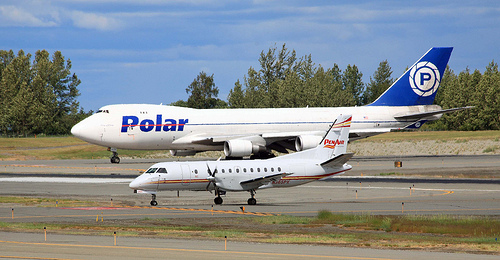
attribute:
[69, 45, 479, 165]
airplane — blue, jet, white, here, cargo carrier, commuter carrier, large, passenger carrier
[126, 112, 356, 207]
airplane — white, striped, here, small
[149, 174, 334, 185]
stripe — orange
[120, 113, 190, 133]
logo — painted, blue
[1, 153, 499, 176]
runway — here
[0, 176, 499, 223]
runway — here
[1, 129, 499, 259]
airport — here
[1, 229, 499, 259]
air strip — here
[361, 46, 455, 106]
tail — blue, white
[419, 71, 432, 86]
letter — p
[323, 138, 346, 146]
writing — red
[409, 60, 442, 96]
design — circle, white